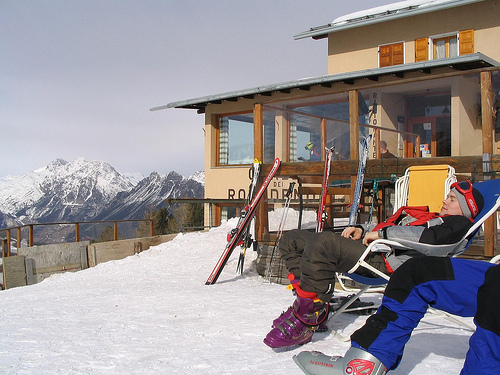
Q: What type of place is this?
A: A ski resort.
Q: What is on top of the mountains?
A: Snow.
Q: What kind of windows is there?
A: Large square.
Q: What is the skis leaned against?
A: Frame.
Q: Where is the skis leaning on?
A: Mountain chalet.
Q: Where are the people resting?
A: Outdoors in ski outfit.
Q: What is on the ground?
A: Snow.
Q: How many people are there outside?
A: Two.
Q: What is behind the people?
A: A building.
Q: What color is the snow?
A: White.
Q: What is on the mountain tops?
A: Snow.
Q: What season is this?
A: Winter.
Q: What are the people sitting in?
A: Lawn chairs.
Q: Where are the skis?
A: Leaning on the railing.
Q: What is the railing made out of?
A: Wood.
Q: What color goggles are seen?
A: Red.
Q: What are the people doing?
A: Sitting.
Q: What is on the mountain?
A: Snow.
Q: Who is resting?
A: A person.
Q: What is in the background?
A: Mountain.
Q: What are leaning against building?
A: Skis.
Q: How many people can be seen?
A: 2.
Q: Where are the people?
A: By a cabin.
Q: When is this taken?
A: Daytime.